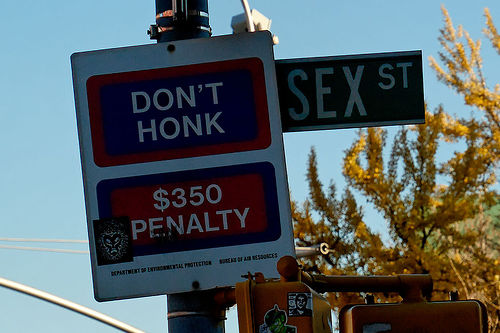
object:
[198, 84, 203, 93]
apostrophe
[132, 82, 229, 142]
letters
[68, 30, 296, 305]
sign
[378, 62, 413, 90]
st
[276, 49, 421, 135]
sign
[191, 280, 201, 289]
bolt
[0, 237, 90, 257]
wires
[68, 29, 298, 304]
citation warning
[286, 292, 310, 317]
sticker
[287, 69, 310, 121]
letter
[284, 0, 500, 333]
leaves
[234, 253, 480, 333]
traffic signal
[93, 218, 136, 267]
sticker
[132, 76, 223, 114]
don't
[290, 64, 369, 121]
sex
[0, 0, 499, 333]
sky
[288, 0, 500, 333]
tree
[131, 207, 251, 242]
letters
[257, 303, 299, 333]
sticker